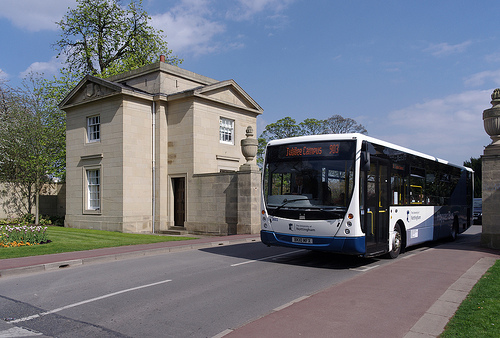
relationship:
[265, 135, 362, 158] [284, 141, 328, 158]
sign displaying destination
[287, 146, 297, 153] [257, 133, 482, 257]
red letter on bus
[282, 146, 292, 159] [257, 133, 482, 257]
letter on bus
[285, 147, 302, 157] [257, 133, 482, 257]
letter on bus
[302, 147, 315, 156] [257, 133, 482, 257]
letter on bus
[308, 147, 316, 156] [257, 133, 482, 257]
letter on bus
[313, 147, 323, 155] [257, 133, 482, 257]
letter on bus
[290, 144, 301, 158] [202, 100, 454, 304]
letter on bus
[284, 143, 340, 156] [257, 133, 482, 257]
red letter on bus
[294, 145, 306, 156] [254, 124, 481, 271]
letter on bus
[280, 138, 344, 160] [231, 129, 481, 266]
letters on bus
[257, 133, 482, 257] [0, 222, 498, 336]
bus on road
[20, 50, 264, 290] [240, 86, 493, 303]
building beside bus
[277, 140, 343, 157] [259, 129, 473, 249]
light on bus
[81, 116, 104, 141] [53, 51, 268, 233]
window on building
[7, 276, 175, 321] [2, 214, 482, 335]
line on road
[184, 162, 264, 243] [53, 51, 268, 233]
wall beside building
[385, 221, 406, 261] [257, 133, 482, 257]
tire of bus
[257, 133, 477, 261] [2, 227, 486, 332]
bus driving down road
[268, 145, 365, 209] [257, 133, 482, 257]
windshield on bus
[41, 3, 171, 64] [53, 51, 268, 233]
tree above building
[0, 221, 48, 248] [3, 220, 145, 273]
flowers in landscape